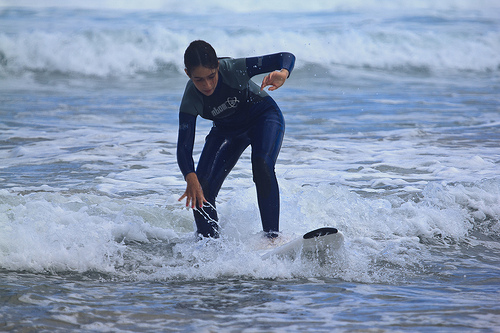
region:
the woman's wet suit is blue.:
[131, 22, 301, 295]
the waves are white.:
[28, 117, 452, 274]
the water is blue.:
[14, 10, 495, 155]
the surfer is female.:
[84, 30, 362, 260]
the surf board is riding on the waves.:
[138, 21, 343, 254]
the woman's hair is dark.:
[162, 26, 226, 108]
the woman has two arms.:
[147, 24, 305, 206]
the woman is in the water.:
[42, 19, 433, 331]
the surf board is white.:
[162, 115, 380, 302]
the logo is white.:
[171, 65, 268, 127]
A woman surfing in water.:
[105, 17, 361, 274]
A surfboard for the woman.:
[248, 202, 362, 284]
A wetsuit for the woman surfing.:
[158, 64, 345, 225]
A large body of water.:
[18, 12, 490, 313]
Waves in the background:
[14, 0, 433, 118]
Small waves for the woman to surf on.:
[15, 163, 498, 283]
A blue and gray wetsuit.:
[187, 57, 316, 230]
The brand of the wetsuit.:
[198, 92, 255, 123]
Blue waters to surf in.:
[6, 84, 498, 130]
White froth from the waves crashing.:
[3, 188, 498, 260]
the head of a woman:
[176, 34, 223, 99]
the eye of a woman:
[207, 71, 216, 78]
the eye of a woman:
[194, 76, 209, 86]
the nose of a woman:
[202, 80, 213, 90]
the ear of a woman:
[181, 66, 192, 83]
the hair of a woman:
[180, 37, 222, 69]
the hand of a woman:
[253, 50, 300, 92]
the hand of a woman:
[173, 92, 218, 230]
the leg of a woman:
[248, 114, 297, 251]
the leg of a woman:
[183, 130, 238, 240]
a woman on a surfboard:
[86, 14, 397, 321]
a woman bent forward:
[136, 24, 368, 248]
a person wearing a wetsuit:
[142, 25, 339, 261]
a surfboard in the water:
[218, 174, 395, 302]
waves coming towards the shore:
[316, 9, 491, 311]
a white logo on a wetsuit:
[199, 83, 249, 128]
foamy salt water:
[0, 194, 148, 282]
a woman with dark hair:
[169, 30, 251, 102]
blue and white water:
[0, 5, 477, 30]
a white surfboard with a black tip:
[263, 204, 375, 274]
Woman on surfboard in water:
[155, 24, 417, 282]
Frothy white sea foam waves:
[34, 176, 146, 326]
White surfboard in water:
[207, 190, 367, 322]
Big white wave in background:
[47, 14, 439, 172]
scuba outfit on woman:
[162, 49, 317, 250]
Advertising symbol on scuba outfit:
[197, 94, 268, 125]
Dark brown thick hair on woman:
[166, 33, 242, 97]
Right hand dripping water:
[152, 153, 275, 282]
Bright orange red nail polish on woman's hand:
[161, 194, 232, 241]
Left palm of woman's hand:
[249, 57, 333, 141]